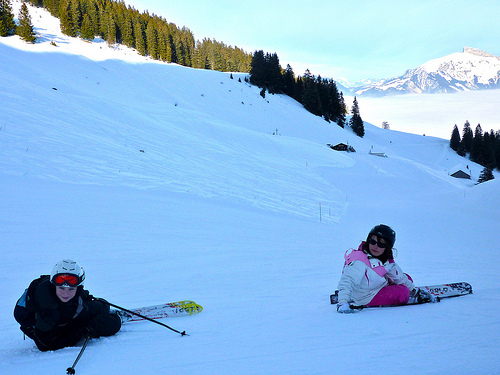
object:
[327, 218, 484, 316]
girl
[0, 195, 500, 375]
ground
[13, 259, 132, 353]
boy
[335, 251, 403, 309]
pink & white jacket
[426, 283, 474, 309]
skis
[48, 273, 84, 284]
red googles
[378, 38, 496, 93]
mountain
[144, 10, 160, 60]
trees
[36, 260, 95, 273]
white helmet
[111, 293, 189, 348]
ski poles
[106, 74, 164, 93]
snow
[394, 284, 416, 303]
knees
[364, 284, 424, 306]
pants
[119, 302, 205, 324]
skis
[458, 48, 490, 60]
ledge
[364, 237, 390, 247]
sunglasses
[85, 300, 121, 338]
black pants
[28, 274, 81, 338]
black jacket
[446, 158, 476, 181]
house